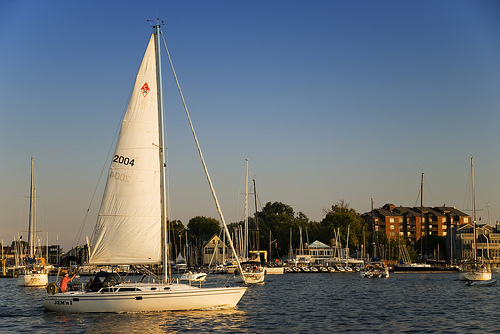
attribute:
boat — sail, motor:
[35, 11, 318, 333]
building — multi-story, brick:
[350, 186, 480, 269]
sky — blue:
[233, 12, 349, 111]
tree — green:
[237, 188, 319, 272]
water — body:
[331, 285, 419, 329]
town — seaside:
[183, 183, 464, 297]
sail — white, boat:
[49, 65, 251, 261]